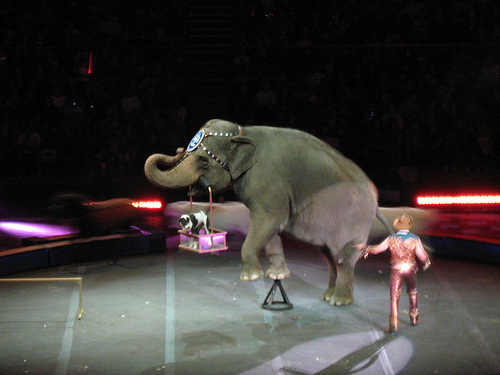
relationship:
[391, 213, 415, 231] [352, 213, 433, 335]
hat on performer